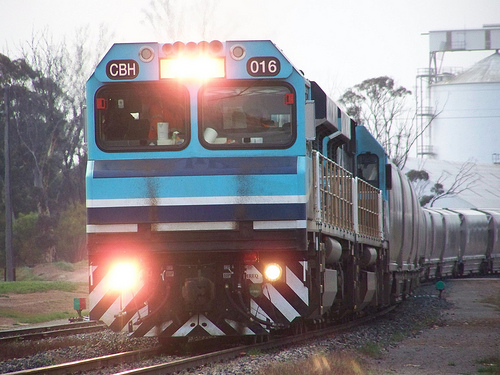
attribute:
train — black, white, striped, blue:
[84, 39, 497, 339]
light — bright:
[108, 258, 141, 292]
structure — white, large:
[398, 22, 498, 208]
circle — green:
[436, 280, 446, 290]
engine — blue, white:
[83, 35, 390, 338]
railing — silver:
[312, 150, 385, 245]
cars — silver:
[390, 158, 500, 302]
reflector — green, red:
[71, 298, 86, 312]